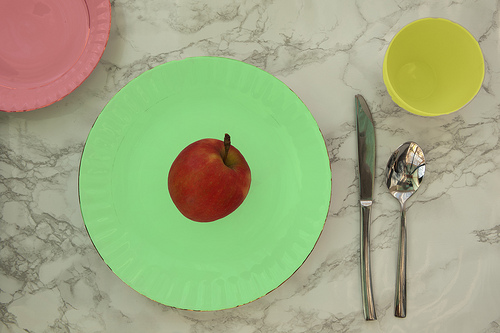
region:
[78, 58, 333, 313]
a green plate with a red apple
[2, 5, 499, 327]
a white marble table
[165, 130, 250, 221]
a red apple with a stem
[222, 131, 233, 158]
the stem of the apple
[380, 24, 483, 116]
a yellow cup on the table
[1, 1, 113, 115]
a small pink plate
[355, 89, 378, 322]
a silver knife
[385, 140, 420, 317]
a silver spoon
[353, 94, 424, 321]
utensils on the marble table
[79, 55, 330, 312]
a green circular plate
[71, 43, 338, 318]
The plate is green.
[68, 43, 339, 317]
The plate is round.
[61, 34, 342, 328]
The plate is in use.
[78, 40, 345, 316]
An apple is on the plate.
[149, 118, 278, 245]
The apple has a stem.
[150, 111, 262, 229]
The apple is red.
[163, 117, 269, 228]
The apple is round.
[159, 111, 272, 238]
The apple is unpeeled.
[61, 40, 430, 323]
The apple is A knife and spoon are lying next to the plate.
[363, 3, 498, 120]
The bowl is empty.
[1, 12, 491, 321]
two plates and a cup on counter top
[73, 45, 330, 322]
a green plate with an apple on it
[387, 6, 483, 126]
a small yellow cup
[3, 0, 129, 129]
a pink dinner plate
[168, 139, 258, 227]
a red apple sitting on plate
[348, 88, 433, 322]
silverware to eat with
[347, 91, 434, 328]
a spoon and a knife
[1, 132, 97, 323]
a marbled counter top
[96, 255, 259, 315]
fluted edge of the green plate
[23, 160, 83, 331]
gray and white counter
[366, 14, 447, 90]
Yellow bowl on counter.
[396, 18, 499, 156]
Round bowl on counter top.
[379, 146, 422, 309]
Silver spoon on counter top.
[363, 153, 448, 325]
Spoon next to knife on counter top.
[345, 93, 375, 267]
Silver knife on counter top.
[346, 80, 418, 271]
Knife next to spoon on counter top.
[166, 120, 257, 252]
Red apple on top of plate.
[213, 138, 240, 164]
Brown stem on red apple.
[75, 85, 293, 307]
Green round plate on counter top.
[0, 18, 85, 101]
Pink plate sitting on counter top.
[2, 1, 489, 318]
a proper table setting for a meal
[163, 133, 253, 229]
a juicey red apple on top of a plate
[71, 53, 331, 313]
a gorgeous apple mint green round plate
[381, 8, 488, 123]
an empty sunshine yellow cup on the table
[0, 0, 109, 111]
a salmon pink round plate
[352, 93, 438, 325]
a setting of shiny silverware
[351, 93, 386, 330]
a thick handled silver butter knife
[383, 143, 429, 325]
a thick handled spoon on top of a marble top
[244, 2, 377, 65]
a gorgeous well maintained marble table top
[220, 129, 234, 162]
a long brown stem to the apple